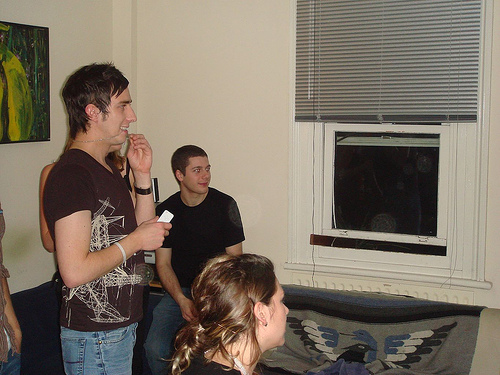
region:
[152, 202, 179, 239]
white wii controller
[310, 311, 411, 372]
bird and snake on a blanket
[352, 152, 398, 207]
dark night outside of the window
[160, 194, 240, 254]
black shirt on a man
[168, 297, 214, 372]
hair tied into a ponytail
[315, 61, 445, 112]
white slatted blinds on a window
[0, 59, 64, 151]
painting hanging on the wall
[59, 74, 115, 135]
brown hair on a man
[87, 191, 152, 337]
brown and white shirt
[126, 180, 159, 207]
wrist watch on a man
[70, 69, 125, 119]
Person has dark hair.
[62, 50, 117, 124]
Person has short hair.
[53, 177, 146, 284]
Person wearing t-shirt.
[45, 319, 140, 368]
Person wearing blue jeans.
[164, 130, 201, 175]
Person has dark hair.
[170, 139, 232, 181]
Person has short hair.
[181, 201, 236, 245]
Person wearing black shirt.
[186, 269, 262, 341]
Person has brown hair.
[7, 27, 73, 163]
Picture hanging on white wall.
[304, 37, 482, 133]
Gray blinds on window.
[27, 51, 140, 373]
man playing nintendo wii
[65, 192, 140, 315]
white designs on black shirt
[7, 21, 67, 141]
painting hanging on rear wall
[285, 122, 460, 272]
small window in wall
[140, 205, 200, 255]
white wii remote in hand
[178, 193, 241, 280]
black t shirt on boy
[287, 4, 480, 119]
raised blinds on window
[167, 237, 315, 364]
blonde hair on girl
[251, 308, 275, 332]
small earring on blonde girl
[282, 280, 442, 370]
bird design on blanket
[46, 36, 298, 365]
people are playing a game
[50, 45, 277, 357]
two men and a woman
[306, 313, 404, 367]
eagle on the blanket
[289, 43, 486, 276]
a window in background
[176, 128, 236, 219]
his hair is dark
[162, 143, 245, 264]
his shirt is black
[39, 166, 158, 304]
his shirt has wire design on it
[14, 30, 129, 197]
a picture on the wall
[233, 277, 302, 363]
she has pierced ears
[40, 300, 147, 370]
his jeans are blue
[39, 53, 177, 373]
person watching a video game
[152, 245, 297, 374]
person watching a video game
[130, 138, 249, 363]
person watching a video game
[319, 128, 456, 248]
window in a room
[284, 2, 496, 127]
window blind in a room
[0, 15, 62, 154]
painting on a wall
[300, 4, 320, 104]
cord on a set of window blinds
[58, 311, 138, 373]
pair of blue jeans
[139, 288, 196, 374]
pair of blue jeans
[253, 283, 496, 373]
blanket on a bed